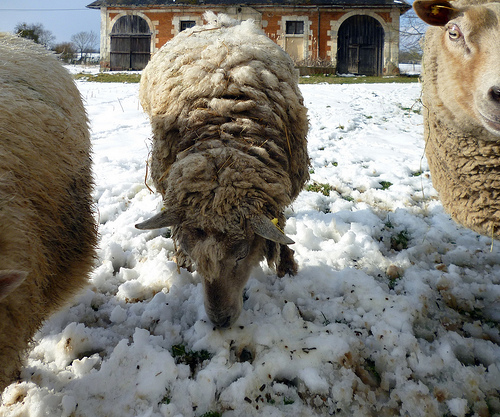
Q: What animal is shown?
A: Sheep.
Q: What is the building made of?
A: Brick.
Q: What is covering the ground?
A: Snow.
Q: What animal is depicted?
A: Sheep.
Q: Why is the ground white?
A: Snow.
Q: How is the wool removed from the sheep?
A: Shears.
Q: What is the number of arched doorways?
A: 2.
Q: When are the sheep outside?
A: Winter day.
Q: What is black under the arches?
A: Doors.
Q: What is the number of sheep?
A: Three.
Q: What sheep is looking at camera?
A: Right side sheep.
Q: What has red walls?
A: Building in background.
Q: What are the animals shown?
A: Sheep.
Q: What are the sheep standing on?
A: Snow.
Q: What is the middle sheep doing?
A: Eating snow.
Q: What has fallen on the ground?
A: Snow.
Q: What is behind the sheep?
A: A building.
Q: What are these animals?
A: Sheep.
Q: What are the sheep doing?
A: Grazing.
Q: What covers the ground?
A: Snow.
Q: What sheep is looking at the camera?
A: The one on the right.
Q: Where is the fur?
A: On the sheep.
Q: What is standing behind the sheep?
A: A building.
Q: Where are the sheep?
A: In a yard in front of a building.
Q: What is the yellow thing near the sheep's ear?
A: Tag.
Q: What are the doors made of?
A: Wood.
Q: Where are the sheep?
A: In a field.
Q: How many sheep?
A: Three.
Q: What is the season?
A: Winter.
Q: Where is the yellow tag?
A: Middle sheep's ear.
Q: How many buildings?
A: One.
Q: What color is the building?
A: Orange and white.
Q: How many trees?
A: Three.